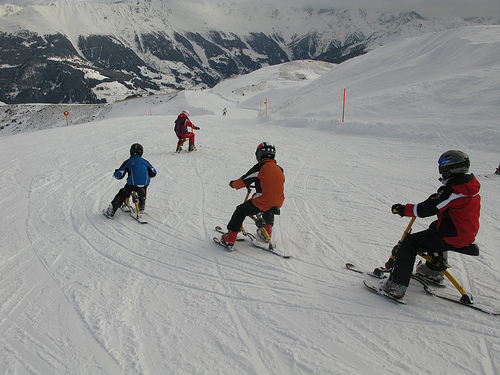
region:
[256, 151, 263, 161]
Black helmet on top of skier's head.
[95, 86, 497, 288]
People skiing down a slope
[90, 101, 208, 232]
People skiing down a slope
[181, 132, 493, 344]
People skiing down a slope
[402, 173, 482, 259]
Person wearing a red jacket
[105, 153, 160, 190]
Person wearing a blue jacket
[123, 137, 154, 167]
Person wearing black helmet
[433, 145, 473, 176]
Person wearing gray helmet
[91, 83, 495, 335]
four people skiing in snow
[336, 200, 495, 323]
ski bike in snow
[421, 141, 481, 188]
helmet on skier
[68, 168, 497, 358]
ski trails in snow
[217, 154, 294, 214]
orange and black coat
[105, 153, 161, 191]
blue and black coat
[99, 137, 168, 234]
child riding a bicycle with skis for wheels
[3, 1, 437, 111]
snow covered mountains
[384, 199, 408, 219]
black gloved hand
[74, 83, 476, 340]
the kids are playing in the snow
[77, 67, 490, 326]
the kids are playing in the snow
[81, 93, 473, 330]
the kids are playing in the snow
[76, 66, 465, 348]
the kids are playing in the snow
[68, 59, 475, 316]
the kids are playing in the snow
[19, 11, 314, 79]
a snow covered mountain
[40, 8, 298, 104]
a snow covered mountain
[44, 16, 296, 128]
a snow covered mountain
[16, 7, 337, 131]
a snow covered mountain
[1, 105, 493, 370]
Ski tracks on the white snow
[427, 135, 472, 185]
Person is wearing a helmet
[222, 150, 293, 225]
An orange, black and white ski jacket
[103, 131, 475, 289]
People on ski bikes.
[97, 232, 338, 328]
Ski marks in the snow.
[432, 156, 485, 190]
Person is wearing a helmet.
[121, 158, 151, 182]
The jacket is blue.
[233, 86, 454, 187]
The ground is covered in snow.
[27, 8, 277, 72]
Snow on the mountain.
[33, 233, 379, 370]
The snow is white.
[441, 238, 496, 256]
The seat is black.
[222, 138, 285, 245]
a boy on skis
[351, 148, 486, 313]
a boy on skis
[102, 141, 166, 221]
a boy on skis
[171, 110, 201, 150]
a boy on skis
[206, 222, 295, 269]
a pair of skis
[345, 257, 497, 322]
a pair of skis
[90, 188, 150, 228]
a pair of skis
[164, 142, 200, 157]
a pair of skis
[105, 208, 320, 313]
stripes in the snow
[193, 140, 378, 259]
stripes in the snow